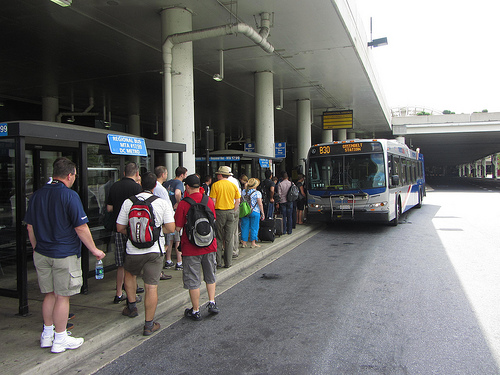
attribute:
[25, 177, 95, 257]
shirt — red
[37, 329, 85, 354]
shoes — white 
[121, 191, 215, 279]
shirt — white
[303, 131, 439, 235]
bus — gray , blue 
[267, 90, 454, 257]
bus — passenger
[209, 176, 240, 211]
shirt — yellow 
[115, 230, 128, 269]
shorts — flannel 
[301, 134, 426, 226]
bus — blue, gray , white , parked 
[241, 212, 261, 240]
pants — blue 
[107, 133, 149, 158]
sign — blue 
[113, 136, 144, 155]
letters — white 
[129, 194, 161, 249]
backpack — red, gray , black 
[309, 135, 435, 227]
bus — silver , blue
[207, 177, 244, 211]
shirt — yellow 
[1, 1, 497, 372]
station — transit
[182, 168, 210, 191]
hat — black